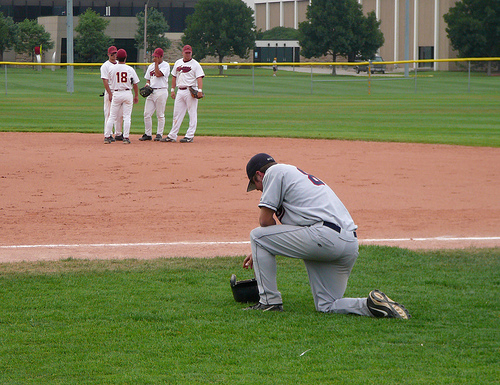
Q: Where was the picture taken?
A: Baseball field.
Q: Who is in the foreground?
A: A man.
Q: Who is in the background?
A: Four men.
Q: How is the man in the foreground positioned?
A: Kneeling.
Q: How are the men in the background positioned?
A: Standing.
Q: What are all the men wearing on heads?
A: Baseball hats.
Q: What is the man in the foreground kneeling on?
A: Grass.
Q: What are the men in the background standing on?
A: Dirt.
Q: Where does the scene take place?
A: At a baseball game.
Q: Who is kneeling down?
A: Player in gray uniform.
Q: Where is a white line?
A: On the dirt.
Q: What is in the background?
A: Trees.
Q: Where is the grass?
A: On a baseball field.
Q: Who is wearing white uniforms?
A: Four players.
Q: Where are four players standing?
A: On the dirt.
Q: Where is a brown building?
A: In the distance.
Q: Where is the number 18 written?
A: On back of a white uniform.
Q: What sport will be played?
A: Baseball.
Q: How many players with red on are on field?
A: 4.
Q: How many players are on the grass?
A: 1.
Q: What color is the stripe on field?
A: White.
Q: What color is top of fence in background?
A: Yellow.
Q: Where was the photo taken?
A: Baseball field.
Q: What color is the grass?
A: Green.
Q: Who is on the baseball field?
A: Male players.